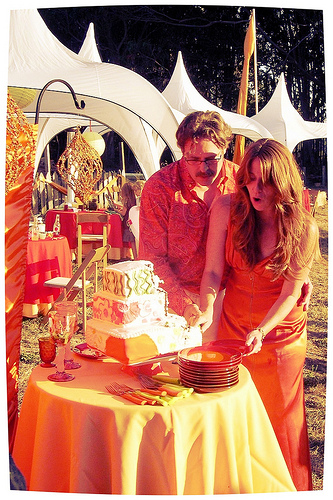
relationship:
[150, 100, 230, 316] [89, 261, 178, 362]
man cutting cake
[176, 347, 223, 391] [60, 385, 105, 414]
plates on top of table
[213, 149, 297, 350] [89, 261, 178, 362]
woman cutting cake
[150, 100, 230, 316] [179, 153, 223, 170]
man wearing glasses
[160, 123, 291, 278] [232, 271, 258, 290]
couple wearing orange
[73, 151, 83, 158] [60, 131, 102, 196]
glitter on chandalier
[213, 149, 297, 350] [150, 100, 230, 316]
woman and man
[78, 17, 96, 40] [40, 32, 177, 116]
points on top of tents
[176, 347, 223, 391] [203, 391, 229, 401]
plates on top of tablecloth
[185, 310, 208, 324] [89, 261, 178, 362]
hands are on cake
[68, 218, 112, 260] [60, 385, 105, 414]
chair next to table